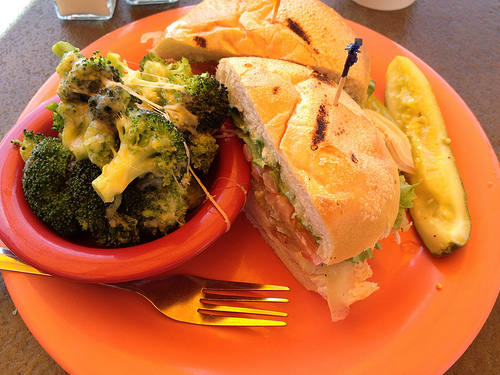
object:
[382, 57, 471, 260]
pickle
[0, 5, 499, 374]
plate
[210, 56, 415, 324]
sandwhich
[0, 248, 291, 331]
fork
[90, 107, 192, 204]
brocolli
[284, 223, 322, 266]
tomato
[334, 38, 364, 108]
toothpick